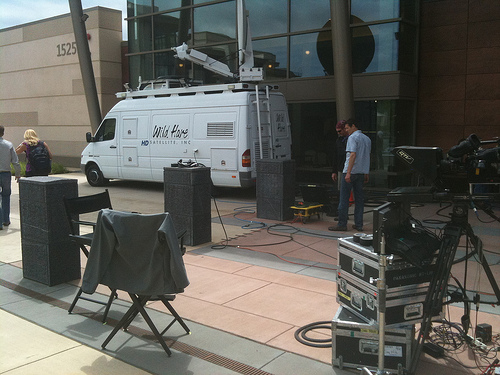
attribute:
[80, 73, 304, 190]
truck — white, large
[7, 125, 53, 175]
woman — walking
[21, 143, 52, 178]
bookbag — black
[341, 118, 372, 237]
man — down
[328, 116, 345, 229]
man — down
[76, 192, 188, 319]
coat — gray, long sleeve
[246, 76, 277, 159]
ladder — white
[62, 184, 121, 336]
chair — black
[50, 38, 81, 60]
number — tan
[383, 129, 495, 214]
camera — high tech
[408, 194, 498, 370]
tripod — black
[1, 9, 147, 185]
building — tan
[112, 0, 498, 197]
building — brown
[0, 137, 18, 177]
shirt — white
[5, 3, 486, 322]
area — movie set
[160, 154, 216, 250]
box — electrical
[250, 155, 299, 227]
box — electrical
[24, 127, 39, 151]
hair — blonde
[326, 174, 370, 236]
jeans — blue